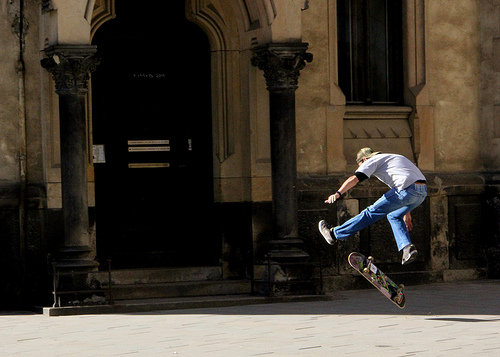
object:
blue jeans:
[333, 183, 428, 252]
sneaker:
[318, 219, 338, 245]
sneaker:
[402, 244, 419, 265]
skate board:
[348, 252, 406, 310]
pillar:
[39, 44, 102, 292]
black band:
[336, 191, 342, 198]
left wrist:
[336, 190, 342, 198]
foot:
[318, 220, 337, 246]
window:
[336, 0, 404, 107]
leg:
[333, 189, 414, 239]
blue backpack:
[337, 238, 413, 309]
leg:
[387, 192, 428, 247]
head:
[356, 147, 382, 167]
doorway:
[89, 0, 222, 272]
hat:
[356, 147, 382, 163]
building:
[0, 0, 499, 317]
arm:
[337, 158, 377, 196]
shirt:
[353, 153, 428, 193]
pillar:
[250, 42, 314, 279]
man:
[318, 147, 427, 265]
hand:
[324, 192, 340, 204]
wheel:
[363, 268, 369, 274]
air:
[25, 9, 467, 190]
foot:
[401, 244, 418, 265]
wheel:
[399, 284, 405, 290]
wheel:
[394, 296, 401, 302]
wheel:
[368, 256, 374, 262]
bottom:
[348, 252, 406, 310]